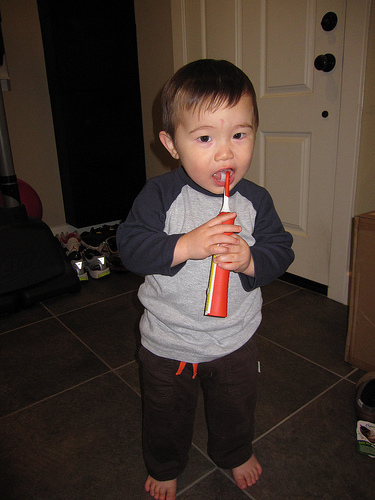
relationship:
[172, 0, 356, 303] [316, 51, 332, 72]
door has knob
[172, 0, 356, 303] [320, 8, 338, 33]
door has deadbolt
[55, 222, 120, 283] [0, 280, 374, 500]
shoes on floor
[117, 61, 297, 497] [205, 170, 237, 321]
toddler holding toothbrush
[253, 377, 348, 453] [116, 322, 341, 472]
grout between tile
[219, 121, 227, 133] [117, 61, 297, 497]
scar on toddler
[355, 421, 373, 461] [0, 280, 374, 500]
magazine on floor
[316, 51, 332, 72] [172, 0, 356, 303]
knob on door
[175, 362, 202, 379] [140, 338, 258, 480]
strings are on pants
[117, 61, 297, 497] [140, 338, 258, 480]
toddler wearing pants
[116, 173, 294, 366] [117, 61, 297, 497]
shirt on toddler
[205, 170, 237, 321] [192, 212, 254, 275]
toothbrush in hands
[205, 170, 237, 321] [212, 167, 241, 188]
toothbrush in mouth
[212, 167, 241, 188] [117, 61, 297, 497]
mouth on toddler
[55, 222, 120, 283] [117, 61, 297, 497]
shoes are behind toddler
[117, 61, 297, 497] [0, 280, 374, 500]
toddler standing floor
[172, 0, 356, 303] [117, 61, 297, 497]
door behind toddler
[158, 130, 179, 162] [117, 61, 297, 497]
ear on toddler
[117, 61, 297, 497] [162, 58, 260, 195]
toddler has head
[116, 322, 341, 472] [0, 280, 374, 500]
tile on floor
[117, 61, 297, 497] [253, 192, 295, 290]
toddler has an arm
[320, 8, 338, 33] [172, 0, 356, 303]
lock on door